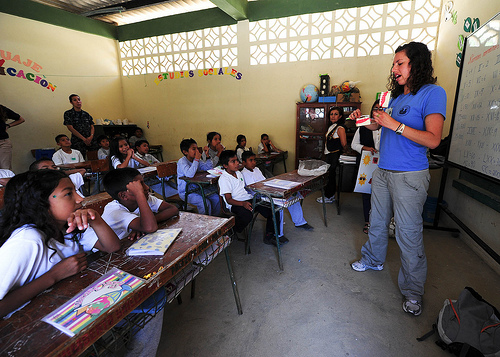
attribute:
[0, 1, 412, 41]
wall border — painted, green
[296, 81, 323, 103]
globe — sitting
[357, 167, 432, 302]
pant — gray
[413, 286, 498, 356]
backpack — grey and black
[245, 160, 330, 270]
desk — sitting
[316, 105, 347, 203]
woman — standing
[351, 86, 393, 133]
cards — red, white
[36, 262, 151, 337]
handbook — colorful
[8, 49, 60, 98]
writing — colorful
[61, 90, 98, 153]
person — wearing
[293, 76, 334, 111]
globe — blue, round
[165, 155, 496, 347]
flooring — concrete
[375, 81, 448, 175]
shirt — blue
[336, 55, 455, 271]
teacher — holding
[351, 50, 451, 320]
girl — giving speech